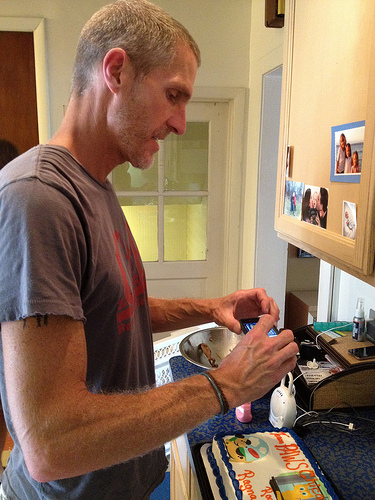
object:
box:
[286, 322, 375, 414]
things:
[345, 344, 375, 364]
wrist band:
[198, 371, 225, 419]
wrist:
[195, 366, 234, 418]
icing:
[206, 426, 341, 500]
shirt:
[0, 143, 170, 500]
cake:
[206, 423, 338, 500]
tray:
[189, 441, 343, 500]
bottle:
[352, 298, 365, 342]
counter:
[168, 354, 374, 500]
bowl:
[177, 325, 245, 373]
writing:
[234, 469, 259, 500]